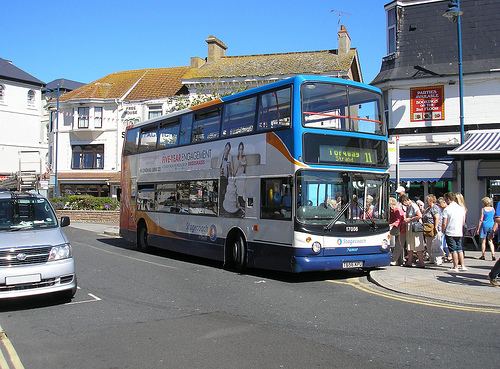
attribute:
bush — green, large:
[51, 189, 102, 211]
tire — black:
[228, 232, 249, 269]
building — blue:
[370, 0, 499, 237]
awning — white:
[447, 129, 497, 156]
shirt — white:
[443, 204, 465, 236]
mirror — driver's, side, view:
[58, 211, 71, 233]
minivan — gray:
[2, 187, 76, 307]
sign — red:
[407, 80, 447, 123]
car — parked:
[1, 206, 87, 279]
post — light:
[450, 5, 467, 150]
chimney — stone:
[195, 27, 245, 70]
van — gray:
[3, 187, 76, 309]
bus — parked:
[119, 71, 394, 278]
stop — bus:
[390, 233, 498, 263]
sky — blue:
[1, 2, 388, 96]